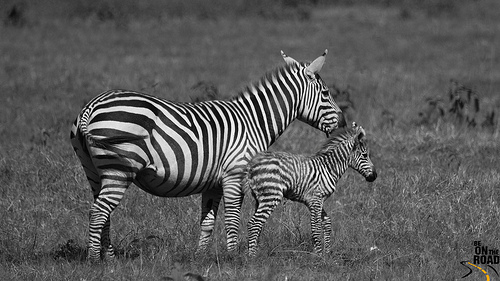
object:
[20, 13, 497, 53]
grass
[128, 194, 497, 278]
grass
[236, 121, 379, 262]
baby zebra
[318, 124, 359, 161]
fur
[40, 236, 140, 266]
shadow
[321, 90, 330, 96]
eye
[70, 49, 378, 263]
zebras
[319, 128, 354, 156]
mane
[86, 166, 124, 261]
leg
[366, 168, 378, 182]
nose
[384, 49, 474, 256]
ground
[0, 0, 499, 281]
grass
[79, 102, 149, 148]
tail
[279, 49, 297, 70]
ear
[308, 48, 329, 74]
ear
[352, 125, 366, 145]
ear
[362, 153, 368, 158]
eye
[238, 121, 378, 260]
baby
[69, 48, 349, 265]
adult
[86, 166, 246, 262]
legs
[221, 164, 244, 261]
leg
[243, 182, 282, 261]
leg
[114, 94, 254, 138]
back